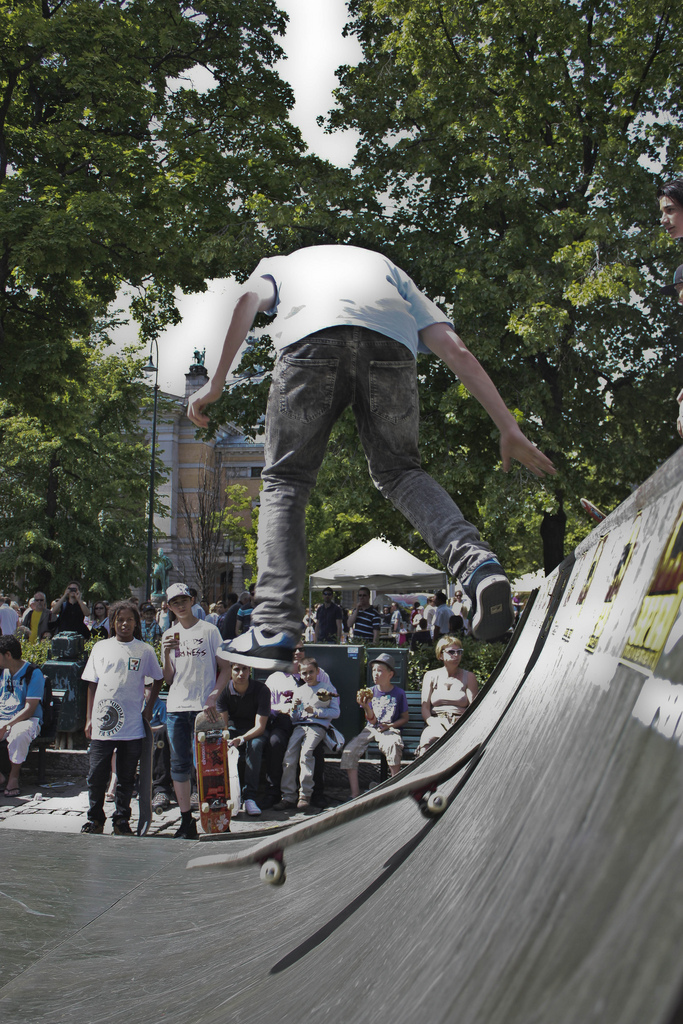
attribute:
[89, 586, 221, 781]
people — watching, looking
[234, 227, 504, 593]
man — skating, jumpin, jumping, performing, flying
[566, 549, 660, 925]
ramp — silver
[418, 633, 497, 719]
woman — watching, looking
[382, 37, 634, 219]
tree — alive, green, lush, full, tall, bushy